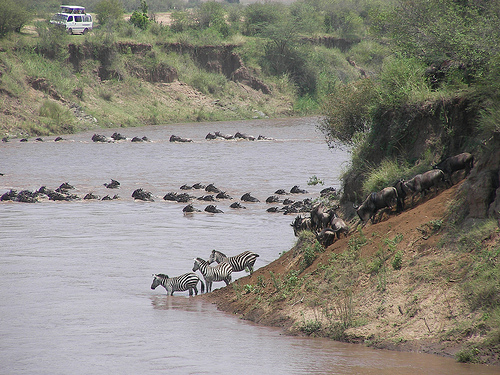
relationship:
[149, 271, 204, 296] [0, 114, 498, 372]
zebra by river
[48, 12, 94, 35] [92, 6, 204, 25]
van on road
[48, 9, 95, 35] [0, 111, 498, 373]
van near water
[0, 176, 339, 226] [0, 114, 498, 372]
animals crossing river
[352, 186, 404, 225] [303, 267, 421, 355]
water buffalo walking hill side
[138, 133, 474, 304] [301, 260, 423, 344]
animals on hill side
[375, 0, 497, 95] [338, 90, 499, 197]
shrubs on cliff edge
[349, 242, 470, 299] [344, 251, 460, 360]
grass on hill side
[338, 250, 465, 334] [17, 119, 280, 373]
hill side by river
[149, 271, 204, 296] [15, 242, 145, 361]
zebra in water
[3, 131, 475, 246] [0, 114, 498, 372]
wildbeasts crossing river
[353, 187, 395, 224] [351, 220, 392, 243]
water buffalo walking hill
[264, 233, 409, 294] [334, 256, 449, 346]
plants growing hill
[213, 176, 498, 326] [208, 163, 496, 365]
dirt on ground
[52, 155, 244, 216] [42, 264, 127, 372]
buffalo on water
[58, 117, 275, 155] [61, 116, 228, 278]
buffalo crossing river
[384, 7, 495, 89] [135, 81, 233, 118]
trees growing river bank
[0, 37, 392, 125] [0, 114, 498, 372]
cliff on river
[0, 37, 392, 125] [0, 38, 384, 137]
cliff on river bank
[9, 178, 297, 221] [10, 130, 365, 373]
wildebeest crossing a river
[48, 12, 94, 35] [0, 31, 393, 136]
van parked on a cliff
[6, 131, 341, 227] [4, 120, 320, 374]
animals crossing a river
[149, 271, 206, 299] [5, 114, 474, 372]
zebra at hole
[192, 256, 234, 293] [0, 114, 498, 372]
zebra entering river